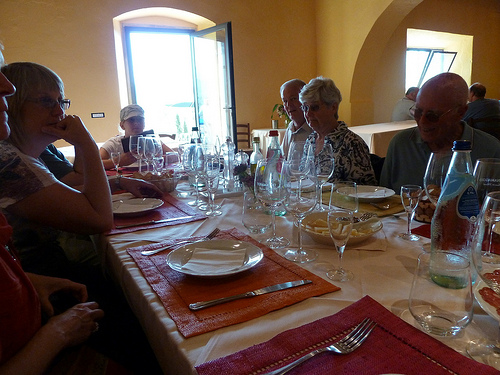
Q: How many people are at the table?
A: Six.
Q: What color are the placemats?
A: Red.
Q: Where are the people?
A: Restaurant.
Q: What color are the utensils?
A: Silver.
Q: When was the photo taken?
A: Afternoon.